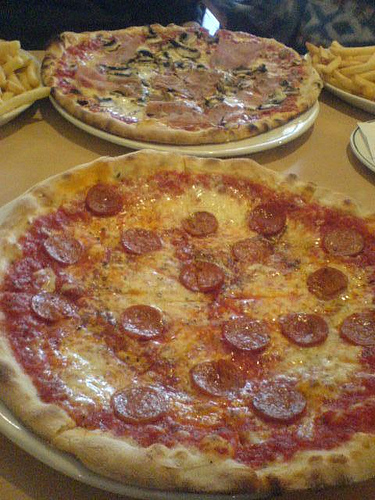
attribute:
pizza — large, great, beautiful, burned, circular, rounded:
[0, 148, 374, 498]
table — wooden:
[1, 37, 374, 499]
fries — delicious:
[0, 38, 47, 110]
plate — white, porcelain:
[2, 102, 40, 125]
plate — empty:
[345, 115, 374, 171]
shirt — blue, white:
[211, 5, 374, 52]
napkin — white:
[358, 118, 374, 161]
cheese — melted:
[164, 178, 243, 218]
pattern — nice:
[304, 8, 366, 46]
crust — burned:
[35, 33, 75, 84]